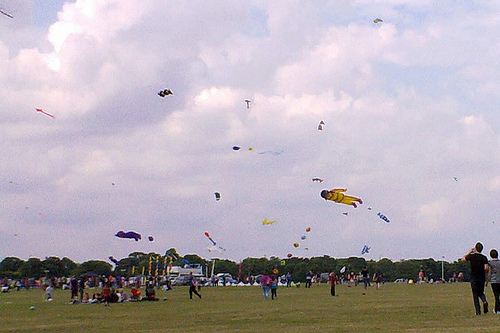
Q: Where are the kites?
A: In the sky.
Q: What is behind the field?
A: Trees.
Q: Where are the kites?
A: In the sky.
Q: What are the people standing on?
A: Grass.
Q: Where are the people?
A: In a field.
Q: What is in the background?
A: A forested area.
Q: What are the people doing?
A: Flying kites.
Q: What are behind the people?
A: Parked cars.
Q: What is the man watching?
A: People flying kites.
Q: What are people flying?
A: Kite.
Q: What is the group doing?
A: Flying kites.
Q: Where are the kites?
A: In sky.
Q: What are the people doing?
A: Flying Kites.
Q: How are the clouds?
A: White.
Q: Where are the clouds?
A: In sky.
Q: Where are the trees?
A: Behind people.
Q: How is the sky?
A: Cloudy.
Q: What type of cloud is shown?
A: Cumulus.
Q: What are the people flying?
A: Kites.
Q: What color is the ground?
A: Green.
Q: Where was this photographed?
A: Park.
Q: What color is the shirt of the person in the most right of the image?
A: Gray.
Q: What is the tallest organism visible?
A: Tree.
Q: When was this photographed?
A: Daytime.